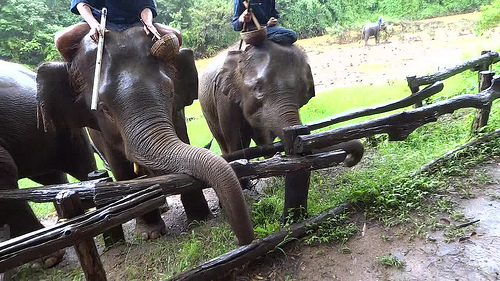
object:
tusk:
[129, 163, 140, 172]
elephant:
[34, 13, 255, 245]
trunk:
[115, 114, 257, 245]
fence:
[0, 48, 499, 280]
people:
[53, 0, 182, 62]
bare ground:
[217, 137, 497, 281]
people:
[230, 0, 297, 46]